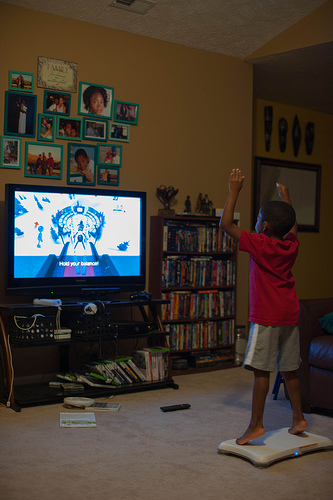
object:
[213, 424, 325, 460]
wii platform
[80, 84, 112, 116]
picture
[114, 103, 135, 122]
picture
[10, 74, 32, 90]
picture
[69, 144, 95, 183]
picture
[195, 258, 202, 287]
movie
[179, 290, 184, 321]
movie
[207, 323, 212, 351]
movie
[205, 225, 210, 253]
movie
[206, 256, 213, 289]
movie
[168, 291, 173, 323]
movie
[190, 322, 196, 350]
movie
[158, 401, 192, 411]
remote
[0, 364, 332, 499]
floor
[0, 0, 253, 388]
wall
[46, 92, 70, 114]
picture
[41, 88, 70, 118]
frame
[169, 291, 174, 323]
movie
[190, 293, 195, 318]
movie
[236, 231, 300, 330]
shirt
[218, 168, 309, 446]
boy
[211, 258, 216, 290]
movie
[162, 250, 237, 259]
shelf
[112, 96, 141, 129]
frame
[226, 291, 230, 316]
movie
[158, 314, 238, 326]
shelf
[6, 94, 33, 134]
picture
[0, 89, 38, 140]
frame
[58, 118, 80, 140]
picture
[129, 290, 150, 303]
controller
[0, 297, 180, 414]
tv stand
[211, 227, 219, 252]
vcr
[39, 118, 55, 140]
picture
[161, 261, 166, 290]
movies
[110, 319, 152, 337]
vcr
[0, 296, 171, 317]
shelf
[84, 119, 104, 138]
picture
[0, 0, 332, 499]
building